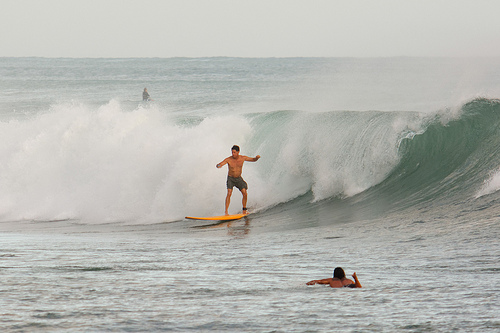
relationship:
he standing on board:
[216, 143, 263, 217] [185, 207, 256, 219]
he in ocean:
[216, 144, 263, 216] [0, 54, 497, 331]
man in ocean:
[306, 266, 363, 288] [0, 54, 497, 331]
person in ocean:
[141, 86, 151, 100] [0, 54, 497, 331]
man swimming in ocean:
[306, 266, 363, 288] [0, 54, 497, 331]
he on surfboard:
[216, 144, 263, 216] [186, 207, 253, 222]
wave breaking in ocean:
[0, 100, 499, 226] [0, 54, 497, 331]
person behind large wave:
[141, 87, 151, 100] [279, 94, 425, 212]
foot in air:
[349, 273, 362, 284] [0, 1, 498, 292]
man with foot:
[306, 266, 363, 288] [349, 273, 362, 284]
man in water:
[306, 266, 363, 288] [0, 54, 500, 331]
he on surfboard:
[216, 144, 263, 216] [183, 204, 268, 231]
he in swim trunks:
[216, 144, 263, 216] [227, 175, 248, 191]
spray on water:
[32, 94, 216, 176] [55, 52, 475, 215]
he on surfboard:
[216, 144, 263, 216] [158, 190, 280, 261]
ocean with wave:
[0, 54, 497, 331] [91, 112, 167, 192]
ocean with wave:
[0, 54, 497, 331] [330, 102, 483, 195]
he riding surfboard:
[216, 144, 263, 216] [184, 211, 248, 221]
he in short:
[216, 144, 263, 216] [227, 176, 249, 190]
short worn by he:
[227, 176, 249, 190] [216, 144, 263, 216]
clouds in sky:
[0, 0, 499, 63] [219, 23, 276, 45]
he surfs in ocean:
[216, 144, 263, 216] [328, 113, 483, 235]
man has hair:
[306, 266, 363, 288] [332, 267, 344, 278]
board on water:
[185, 211, 248, 222] [0, 54, 500, 331]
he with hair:
[216, 144, 263, 216] [335, 269, 346, 279]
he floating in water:
[216, 144, 263, 216] [222, 248, 434, 323]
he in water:
[216, 144, 263, 216] [9, 60, 472, 310]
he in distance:
[216, 144, 263, 216] [15, 57, 482, 131]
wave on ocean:
[283, 108, 449, 206] [8, 56, 480, 315]